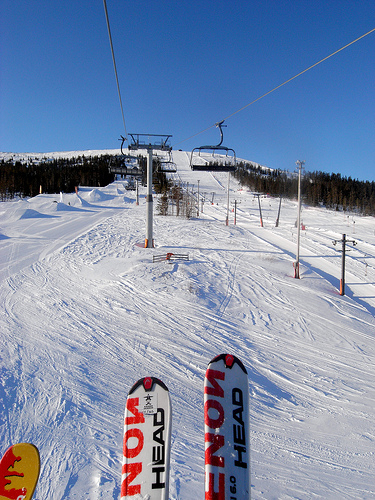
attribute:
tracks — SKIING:
[22, 282, 259, 384]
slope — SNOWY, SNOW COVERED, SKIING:
[8, 152, 356, 489]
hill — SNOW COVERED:
[12, 147, 363, 347]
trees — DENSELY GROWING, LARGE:
[1, 146, 146, 203]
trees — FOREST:
[223, 165, 363, 207]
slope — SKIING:
[15, 137, 347, 361]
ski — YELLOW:
[7, 437, 45, 487]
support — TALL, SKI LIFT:
[119, 130, 183, 249]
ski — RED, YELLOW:
[1, 435, 54, 498]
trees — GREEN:
[203, 155, 363, 213]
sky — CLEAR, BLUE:
[6, 11, 363, 153]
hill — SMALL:
[87, 186, 110, 198]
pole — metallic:
[292, 158, 304, 277]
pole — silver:
[295, 160, 305, 276]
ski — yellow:
[0, 441, 41, 498]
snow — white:
[1, 147, 373, 496]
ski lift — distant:
[189, 120, 237, 172]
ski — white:
[203, 351, 250, 497]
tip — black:
[207, 353, 247, 374]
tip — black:
[127, 376, 168, 393]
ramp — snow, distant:
[83, 187, 112, 204]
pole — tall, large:
[144, 147, 155, 247]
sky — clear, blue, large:
[0, 0, 372, 184]